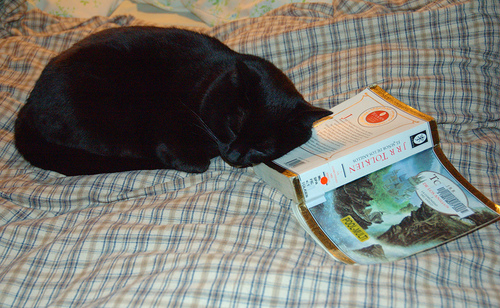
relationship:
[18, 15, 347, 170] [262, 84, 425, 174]
cat using cover book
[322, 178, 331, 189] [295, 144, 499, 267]
drop on cover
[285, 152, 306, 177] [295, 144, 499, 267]
barcode near cover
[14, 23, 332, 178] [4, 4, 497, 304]
cat laying on bed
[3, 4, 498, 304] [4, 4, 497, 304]
sheets are on bed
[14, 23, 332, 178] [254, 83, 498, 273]
cat laying on novel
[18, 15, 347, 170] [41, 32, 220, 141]
cat has fur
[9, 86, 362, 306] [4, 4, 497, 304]
blanket covering bed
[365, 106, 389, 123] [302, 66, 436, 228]
circle on back of book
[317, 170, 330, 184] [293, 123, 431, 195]
circle on spine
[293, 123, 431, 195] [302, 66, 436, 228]
spine of book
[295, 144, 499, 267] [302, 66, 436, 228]
cover of book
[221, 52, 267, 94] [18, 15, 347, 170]
ear on cat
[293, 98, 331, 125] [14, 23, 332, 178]
ear on cat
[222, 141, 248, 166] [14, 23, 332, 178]
nose on cat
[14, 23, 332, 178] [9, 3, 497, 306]
cat on cot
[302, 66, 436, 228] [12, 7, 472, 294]
book on bed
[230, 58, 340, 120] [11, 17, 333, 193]
ears on cat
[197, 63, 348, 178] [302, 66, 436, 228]
head on book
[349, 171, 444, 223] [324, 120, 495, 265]
waterfalls on cover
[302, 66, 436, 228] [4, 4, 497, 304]
book on bed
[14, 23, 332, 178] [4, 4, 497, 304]
cat sleeping on bed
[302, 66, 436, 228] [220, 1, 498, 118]
book on bed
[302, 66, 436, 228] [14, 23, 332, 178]
book next to cat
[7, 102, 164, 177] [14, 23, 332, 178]
tail of cat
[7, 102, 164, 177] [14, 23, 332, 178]
tail under cat